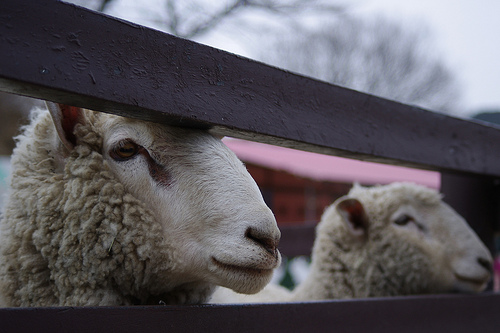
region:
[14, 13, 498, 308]
two sheep looking out of a fence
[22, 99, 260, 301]
the head of a white sheep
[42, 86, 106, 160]
the ear of a white sheep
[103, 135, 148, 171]
the eye of a white sheep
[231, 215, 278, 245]
the nose of a white sheep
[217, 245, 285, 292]
the mouth of a white sheep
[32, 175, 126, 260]
the wool of a white sheep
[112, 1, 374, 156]
a wooden plank of a fence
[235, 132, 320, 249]
a red barn in the distance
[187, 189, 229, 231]
the fur of a white sheep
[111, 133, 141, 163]
The sheeps eye is yellow and black.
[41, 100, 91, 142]
The inside of the sheeps ear is pink.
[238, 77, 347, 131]
The fence is made from wood.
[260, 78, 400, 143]
The fence is brown.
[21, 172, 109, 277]
The sheeps wool is white.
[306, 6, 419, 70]
The tree in the background is blurry.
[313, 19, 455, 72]
The tree in the background has no leaves.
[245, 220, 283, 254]
The sheeps nose is brown.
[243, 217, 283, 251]
The sheeps nose is small.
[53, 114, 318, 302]
The sheeps face is white.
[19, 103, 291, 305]
Sheep peering through fence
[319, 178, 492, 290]
Sheep looking through fence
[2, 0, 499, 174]
Brown wooden fence board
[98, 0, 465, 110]
Tops of trees in distance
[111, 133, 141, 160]
Brown eye on sheep's head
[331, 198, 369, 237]
Ear on side of sheep's head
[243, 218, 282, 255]
Nose on white sheep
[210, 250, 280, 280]
Mouth on white sheep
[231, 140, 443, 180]
Red roof behind fence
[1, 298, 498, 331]
Lower board on fence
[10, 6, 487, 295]
The sheep are looking through the fence.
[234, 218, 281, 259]
The nose is brown.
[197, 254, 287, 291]
The mouth is closed.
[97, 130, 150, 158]
His eyes are black.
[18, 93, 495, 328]
They are poking their heads through.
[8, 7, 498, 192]
The fence is wood.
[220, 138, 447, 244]
The building is in the background.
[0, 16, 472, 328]
The sheep are white.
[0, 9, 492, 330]
The fence is low.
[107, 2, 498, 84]
The trees are looking through.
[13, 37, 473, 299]
Sheep looking through the fence.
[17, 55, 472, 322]
Two sheep by the fence.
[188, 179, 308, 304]
Nose on the sheep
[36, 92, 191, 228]
Eye and ear on the sheep.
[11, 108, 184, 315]
Fur on the sheep.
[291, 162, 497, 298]
Sheep in the background.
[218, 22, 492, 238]
Fence in front of the sheep.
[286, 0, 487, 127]
Trees in the background.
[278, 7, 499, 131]
No leaves on the trees.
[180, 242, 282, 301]
Mouth of the sheep.